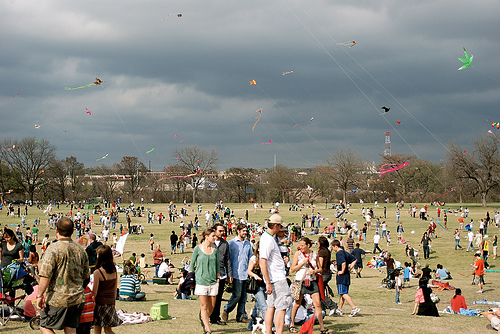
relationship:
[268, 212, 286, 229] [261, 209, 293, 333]
cap on a man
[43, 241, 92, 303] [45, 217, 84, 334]
shirt on a man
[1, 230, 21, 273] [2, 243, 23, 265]
woman in shirt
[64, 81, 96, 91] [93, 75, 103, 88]
tail of kite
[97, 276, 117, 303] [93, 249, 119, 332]
shirt on a girl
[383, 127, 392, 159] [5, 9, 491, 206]
tower in distance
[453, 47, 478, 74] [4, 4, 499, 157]
kite in sky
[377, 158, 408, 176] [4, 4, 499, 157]
kite in sky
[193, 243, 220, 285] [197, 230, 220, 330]
shirt on a woman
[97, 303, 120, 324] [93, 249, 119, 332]
skirt on a girl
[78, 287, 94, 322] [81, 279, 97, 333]
shirt on a boy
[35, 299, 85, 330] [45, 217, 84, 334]
pants are on a man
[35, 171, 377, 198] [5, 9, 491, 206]
buildings in distance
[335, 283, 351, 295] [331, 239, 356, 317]
shorts are on a man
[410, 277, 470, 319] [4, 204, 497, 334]
people are on grass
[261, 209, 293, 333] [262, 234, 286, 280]
man wearing shirt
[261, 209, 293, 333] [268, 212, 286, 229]
man wearing hat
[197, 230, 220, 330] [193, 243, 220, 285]
woman wearing shirt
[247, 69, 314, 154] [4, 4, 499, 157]
kites in sky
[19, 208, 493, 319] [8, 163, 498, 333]
crowd at a park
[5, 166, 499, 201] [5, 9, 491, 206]
trees in distance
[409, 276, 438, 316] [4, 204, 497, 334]
woman on grass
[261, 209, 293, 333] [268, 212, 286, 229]
man wearing cap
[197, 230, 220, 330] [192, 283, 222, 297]
woman wearing shorts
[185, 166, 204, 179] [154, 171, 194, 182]
kite with tail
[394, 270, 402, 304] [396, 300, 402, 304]
kid wearing sneakers